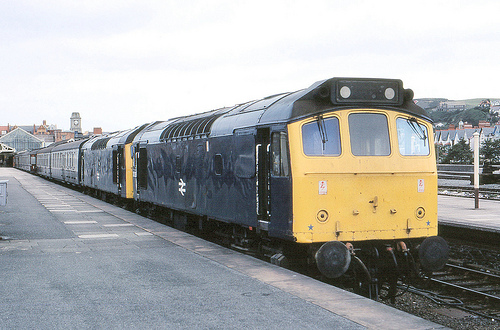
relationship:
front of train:
[293, 81, 438, 242] [8, 75, 450, 302]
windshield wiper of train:
[410, 115, 429, 148] [8, 75, 450, 302]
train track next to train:
[370, 260, 499, 329] [20, 80, 453, 265]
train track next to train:
[449, 260, 497, 286] [20, 80, 453, 265]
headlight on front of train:
[340, 86, 351, 100] [20, 80, 453, 265]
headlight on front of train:
[385, 88, 395, 99] [20, 80, 453, 265]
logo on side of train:
[156, 164, 198, 206] [12, 78, 438, 278]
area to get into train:
[254, 125, 274, 231] [8, 75, 450, 302]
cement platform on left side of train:
[50, 232, 151, 328] [20, 80, 453, 265]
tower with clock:
[66, 110, 84, 133] [69, 118, 85, 126]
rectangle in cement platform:
[105, 223, 151, 237] [0, 166, 457, 329]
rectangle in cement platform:
[61, 220, 117, 237] [0, 166, 457, 329]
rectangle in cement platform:
[50, 210, 96, 220] [0, 166, 457, 329]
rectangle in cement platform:
[42, 206, 78, 213] [0, 166, 457, 329]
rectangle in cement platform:
[35, 196, 71, 206] [0, 166, 457, 329]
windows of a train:
[299, 111, 431, 158] [8, 75, 450, 302]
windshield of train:
[299, 111, 431, 157] [8, 75, 450, 302]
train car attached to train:
[134, 75, 446, 307] [8, 75, 450, 302]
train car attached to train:
[76, 119, 163, 206] [8, 75, 450, 302]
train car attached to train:
[38, 133, 89, 188] [8, 75, 450, 302]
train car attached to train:
[10, 149, 38, 177] [8, 75, 450, 302]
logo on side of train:
[173, 177, 188, 197] [8, 75, 450, 302]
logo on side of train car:
[173, 177, 188, 197] [127, 75, 449, 304]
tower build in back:
[56, 100, 97, 144] [4, 104, 125, 144]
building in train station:
[4, 110, 106, 184] [1, 167, 431, 328]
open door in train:
[253, 125, 275, 232] [28, 81, 455, 289]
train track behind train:
[439, 171, 497, 196] [78, 34, 478, 294]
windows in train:
[298, 107, 430, 159] [20, 80, 453, 265]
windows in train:
[53, 152, 77, 171] [20, 80, 453, 265]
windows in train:
[33, 153, 47, 168] [20, 80, 453, 265]